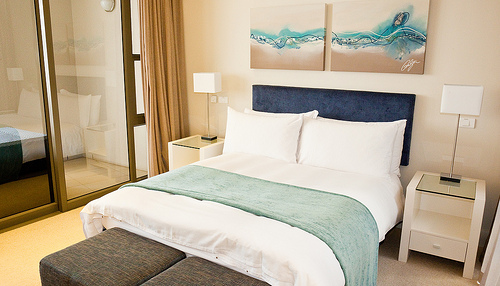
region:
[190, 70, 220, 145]
a lamp on a night table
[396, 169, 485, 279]
a wooden night table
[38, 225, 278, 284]
two poufs at the end of a bed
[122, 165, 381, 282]
a green blanket on a bed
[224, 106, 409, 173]
white pillows on a bed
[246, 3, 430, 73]
two paintings on a wall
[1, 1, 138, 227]
a bronze sliding door with a mirror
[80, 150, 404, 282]
a white cover-bed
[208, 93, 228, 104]
light switches on a wall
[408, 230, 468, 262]
a drawer on a wooden table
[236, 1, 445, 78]
painting on wall of room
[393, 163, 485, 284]
light stand beside bed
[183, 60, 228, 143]
lamp on side of bed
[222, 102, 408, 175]
pillows at head of bed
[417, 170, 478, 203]
glass table top on stand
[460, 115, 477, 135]
control switch for room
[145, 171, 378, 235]
green blanket on top of bed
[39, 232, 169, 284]
end rest at foot of bed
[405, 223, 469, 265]
drawer at bottom of stand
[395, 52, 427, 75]
artist signature on painting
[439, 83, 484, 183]
lamp on the right table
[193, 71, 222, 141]
lamp on the left table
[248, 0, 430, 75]
two matching paintings on the wall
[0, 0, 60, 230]
a sliding glass door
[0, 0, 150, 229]
a series of window panels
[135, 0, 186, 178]
a beige curtain over the windows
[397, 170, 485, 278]
a white nightstand on the right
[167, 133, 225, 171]
a white nightstand on the left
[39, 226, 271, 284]
gray ottomans at the foot of the bed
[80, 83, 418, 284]
a large bed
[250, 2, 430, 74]
the two pictures above the bed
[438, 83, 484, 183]
the lamp on the night stand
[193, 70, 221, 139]
the lamp on the night stand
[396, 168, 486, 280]
the night stand next to the bed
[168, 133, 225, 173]
the night stand next to the bed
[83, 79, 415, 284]
the made up bed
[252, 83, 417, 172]
the head board at the head of the bed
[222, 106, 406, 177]
the pillows on the bed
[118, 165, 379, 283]
the blanket draped over the bed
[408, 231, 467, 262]
the drawer at the bottom of the night stand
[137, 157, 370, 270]
blue blanket draped over bed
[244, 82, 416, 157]
blue headboard of bed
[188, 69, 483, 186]
two lamps on nightstands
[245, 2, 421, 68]
two paintings on the wall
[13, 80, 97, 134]
pillows reflected on glass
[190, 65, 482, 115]
two white lampshades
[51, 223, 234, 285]
gray bench at end of bed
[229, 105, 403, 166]
four white pillows on bed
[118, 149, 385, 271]
white bedspread on bed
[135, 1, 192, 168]
tan curtains pulled back